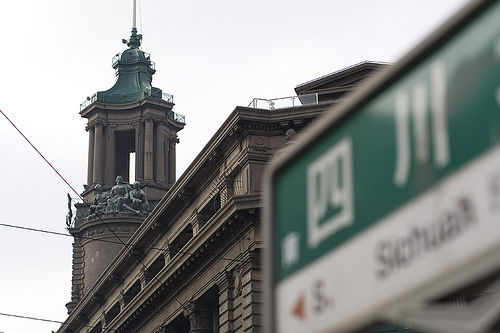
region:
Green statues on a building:
[84, 174, 154, 218]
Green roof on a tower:
[88, 26, 170, 117]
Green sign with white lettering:
[259, 40, 499, 328]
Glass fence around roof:
[239, 91, 322, 113]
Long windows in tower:
[106, 121, 143, 186]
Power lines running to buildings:
[5, 115, 225, 330]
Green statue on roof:
[122, 25, 147, 51]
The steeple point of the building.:
[112, 2, 143, 32]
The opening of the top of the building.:
[117, 126, 134, 180]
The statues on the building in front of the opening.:
[80, 172, 150, 216]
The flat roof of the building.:
[30, 90, 348, 328]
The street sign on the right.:
[247, 6, 491, 327]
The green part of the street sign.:
[263, 10, 498, 272]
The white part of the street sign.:
[273, 165, 498, 329]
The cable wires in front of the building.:
[0, 103, 241, 330]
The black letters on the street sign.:
[243, 170, 497, 330]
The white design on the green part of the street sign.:
[276, 69, 494, 264]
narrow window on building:
[72, 311, 106, 332]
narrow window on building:
[117, 272, 147, 302]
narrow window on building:
[140, 256, 172, 276]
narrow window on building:
[167, 219, 204, 264]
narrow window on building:
[164, 218, 195, 262]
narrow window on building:
[108, 126, 140, 190]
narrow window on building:
[190, 279, 227, 330]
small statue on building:
[97, 172, 129, 213]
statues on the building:
[83, 167, 159, 216]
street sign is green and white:
[260, 1, 498, 331]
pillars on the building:
[85, 116, 179, 191]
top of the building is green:
[91, 25, 164, 99]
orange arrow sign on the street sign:
[290, 293, 310, 321]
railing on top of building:
[245, 91, 323, 110]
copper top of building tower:
[68, 3, 200, 183]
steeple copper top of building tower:
[119, 1, 149, 63]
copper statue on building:
[76, 170, 163, 220]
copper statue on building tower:
[82, 19, 184, 216]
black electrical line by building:
[15, 214, 252, 270]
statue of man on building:
[81, 179, 111, 219]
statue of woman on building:
[104, 170, 131, 217]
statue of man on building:
[128, 177, 155, 220]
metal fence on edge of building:
[232, 82, 339, 124]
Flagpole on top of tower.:
[123, 3, 148, 50]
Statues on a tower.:
[89, 175, 159, 227]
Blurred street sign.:
[251, 48, 491, 327]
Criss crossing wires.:
[38, 179, 170, 296]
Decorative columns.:
[132, 100, 167, 181]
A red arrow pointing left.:
[285, 286, 333, 331]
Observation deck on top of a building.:
[247, 87, 342, 117]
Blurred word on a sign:
[366, 190, 496, 280]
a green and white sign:
[228, 3, 498, 255]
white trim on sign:
[268, 150, 497, 327]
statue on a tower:
[81, 171, 156, 219]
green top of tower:
[73, 40, 177, 113]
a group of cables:
[17, 106, 231, 331]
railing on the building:
[239, 87, 340, 108]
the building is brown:
[41, 115, 289, 332]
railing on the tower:
[76, 84, 191, 119]